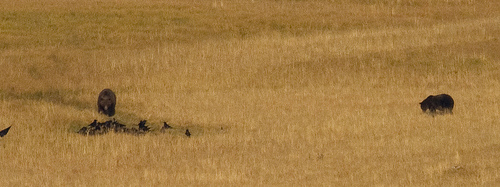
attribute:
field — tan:
[0, 0, 499, 185]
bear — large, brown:
[94, 81, 118, 119]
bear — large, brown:
[418, 90, 453, 112]